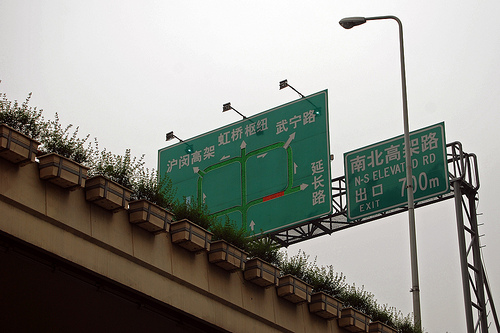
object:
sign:
[153, 90, 333, 233]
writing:
[307, 159, 328, 206]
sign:
[342, 120, 449, 220]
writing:
[349, 130, 439, 171]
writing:
[355, 160, 422, 183]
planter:
[0, 121, 40, 169]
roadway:
[0, 130, 415, 332]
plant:
[0, 84, 44, 135]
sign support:
[264, 141, 498, 332]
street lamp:
[338, 14, 425, 332]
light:
[312, 108, 323, 118]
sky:
[0, 0, 496, 332]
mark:
[261, 189, 285, 203]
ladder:
[452, 148, 495, 332]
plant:
[42, 112, 94, 163]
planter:
[35, 153, 89, 190]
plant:
[98, 145, 144, 186]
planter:
[84, 175, 134, 213]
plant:
[134, 167, 180, 211]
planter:
[129, 199, 173, 237]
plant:
[173, 194, 217, 229]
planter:
[172, 217, 216, 252]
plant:
[214, 218, 253, 251]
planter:
[208, 237, 249, 274]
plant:
[249, 230, 286, 265]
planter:
[244, 257, 281, 289]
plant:
[282, 250, 317, 282]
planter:
[276, 274, 313, 306]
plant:
[312, 264, 347, 296]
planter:
[310, 287, 345, 320]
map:
[190, 133, 305, 235]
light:
[338, 14, 367, 31]